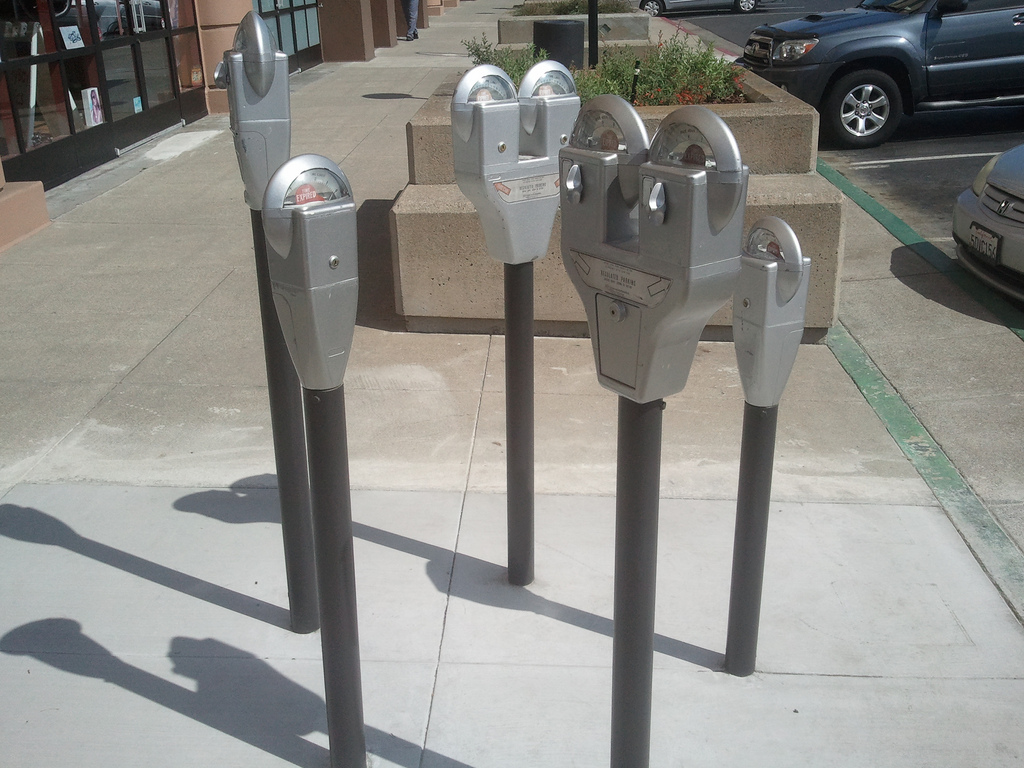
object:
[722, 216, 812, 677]
parking meter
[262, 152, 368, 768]
parking meter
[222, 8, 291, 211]
parking meter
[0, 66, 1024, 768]
sidewalk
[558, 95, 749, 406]
parking meter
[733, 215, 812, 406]
parking meter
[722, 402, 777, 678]
pole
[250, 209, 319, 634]
pole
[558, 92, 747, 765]
meter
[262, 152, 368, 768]
meter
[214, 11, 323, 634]
meter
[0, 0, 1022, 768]
ground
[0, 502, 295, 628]
shadow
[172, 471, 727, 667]
shadow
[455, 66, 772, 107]
plants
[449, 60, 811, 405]
planter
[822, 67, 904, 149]
tire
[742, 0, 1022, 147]
car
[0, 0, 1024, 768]
outdoors scene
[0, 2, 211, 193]
building window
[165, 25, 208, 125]
building window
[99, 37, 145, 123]
building window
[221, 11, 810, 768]
parking meters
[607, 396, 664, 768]
pole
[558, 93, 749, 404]
meter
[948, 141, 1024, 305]
car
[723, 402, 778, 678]
metal pole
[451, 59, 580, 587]
parking meter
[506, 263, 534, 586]
metal pole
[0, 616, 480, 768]
shadow